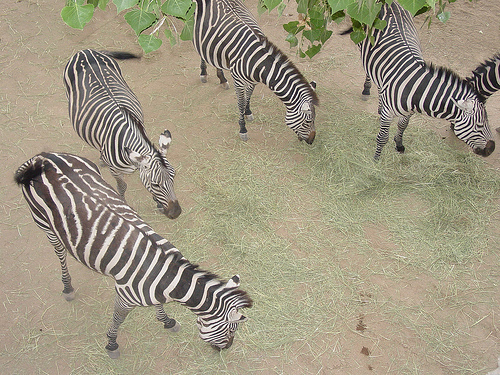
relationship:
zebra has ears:
[62, 44, 193, 209] [116, 129, 178, 168]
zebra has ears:
[186, 0, 335, 176] [294, 75, 320, 114]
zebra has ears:
[447, 88, 484, 111] [436, 75, 484, 118]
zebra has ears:
[15, 152, 253, 356] [223, 272, 243, 328]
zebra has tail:
[15, 152, 253, 356] [10, 145, 42, 188]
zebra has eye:
[62, 44, 193, 209] [142, 174, 165, 191]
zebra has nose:
[62, 44, 193, 209] [157, 199, 194, 224]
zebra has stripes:
[62, 44, 193, 209] [61, 63, 123, 133]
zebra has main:
[186, 0, 335, 176] [264, 32, 316, 86]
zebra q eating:
[15, 152, 253, 356] [231, 328, 271, 356]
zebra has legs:
[447, 88, 484, 111] [356, 97, 410, 156]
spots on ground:
[348, 306, 379, 363] [258, 168, 488, 373]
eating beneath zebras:
[231, 328, 296, 356] [5, 6, 490, 355]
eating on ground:
[231, 328, 296, 356] [258, 168, 488, 373]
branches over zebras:
[63, 1, 474, 41] [5, 6, 490, 355]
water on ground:
[346, 302, 391, 369] [258, 168, 488, 373]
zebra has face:
[62, 44, 193, 209] [138, 174, 192, 224]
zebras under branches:
[5, 6, 490, 355] [63, 1, 474, 41]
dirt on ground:
[371, 268, 424, 302] [258, 168, 488, 373]